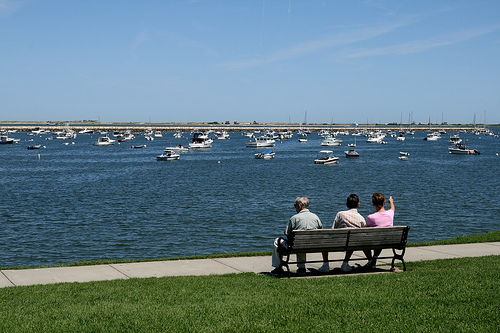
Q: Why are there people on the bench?
A: They are looking at the boats.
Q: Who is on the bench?
A: Three people.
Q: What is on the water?
A: Boats.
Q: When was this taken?
A: During the day.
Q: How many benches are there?
A: One.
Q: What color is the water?
A: Blue.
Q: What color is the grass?
A: Green.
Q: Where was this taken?
A: At a park.